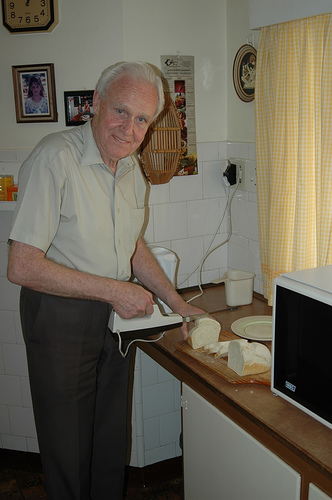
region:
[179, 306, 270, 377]
Bread on a cutting board.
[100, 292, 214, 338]
The man is holding a bread knife.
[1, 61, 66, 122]
A picture of a girl on the wall.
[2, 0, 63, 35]
Clock on the wall.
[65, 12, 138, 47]
The wall is white.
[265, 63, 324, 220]
The curtain is yellow and white.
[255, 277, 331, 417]
A microwave on the counter.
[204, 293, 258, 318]
The counter is wooden.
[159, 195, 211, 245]
White tile on the wall.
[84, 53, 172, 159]
The man has white hair.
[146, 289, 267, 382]
slicing bread on a cutting board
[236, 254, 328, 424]
White microwave on the counter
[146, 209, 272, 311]
Tiles on the wall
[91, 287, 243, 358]
Using an electric slicer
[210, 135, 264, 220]
Cords are plugged into the socket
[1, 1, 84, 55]
Clock on the wall behind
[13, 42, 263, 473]
Neatly dressed gentleman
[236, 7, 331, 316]
Yellow checkered curtains covering the window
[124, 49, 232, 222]
Wooden basket hangs on the wall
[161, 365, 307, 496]
White cabinet door below the counter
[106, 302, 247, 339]
electric carving knife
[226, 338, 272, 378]
loaf of white bread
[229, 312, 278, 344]
small white plate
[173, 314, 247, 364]
loaf of bread being sliced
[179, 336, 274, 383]
small wood cutting board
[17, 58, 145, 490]
older man cutting bread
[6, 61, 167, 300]
older man in short sleeved shirt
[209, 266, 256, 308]
white plastic measuring cup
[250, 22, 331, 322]
yellow gingham checked curtain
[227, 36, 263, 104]
decorative plate hung from wall hook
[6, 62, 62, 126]
framed photo of little girl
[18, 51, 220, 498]
senior man wearing brown pants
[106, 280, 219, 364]
electric carving knife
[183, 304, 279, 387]
loaf of bread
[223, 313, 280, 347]
white empty plate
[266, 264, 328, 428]
black and white microwave oven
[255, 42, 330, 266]
yellow and white gingham curtains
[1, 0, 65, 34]
brown and tan wall clock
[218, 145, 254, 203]
electrical outlet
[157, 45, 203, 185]
poster hanging on the wall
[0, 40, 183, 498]
Man is smiling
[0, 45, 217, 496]
Man holds an electric knife in right hand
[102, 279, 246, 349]
Knife is electric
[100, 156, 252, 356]
Electric knife is plug in electric outlet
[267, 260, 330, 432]
Microwave on a table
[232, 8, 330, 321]
Yellow curtain covers a window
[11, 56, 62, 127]
Picture of a female hangs on wall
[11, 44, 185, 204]
Man has gray hair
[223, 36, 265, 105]
Picture is round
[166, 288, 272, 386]
Bread is cut